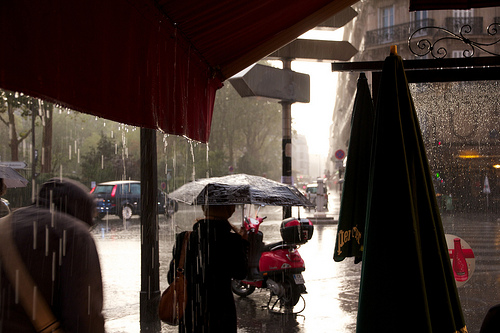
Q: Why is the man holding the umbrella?
A: It's raining.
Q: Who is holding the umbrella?
A: The person wearing black.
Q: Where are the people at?
A: On a sidewalk.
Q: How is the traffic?
A: Busy.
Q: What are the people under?
A: An awning.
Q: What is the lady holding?
A: An umbrella.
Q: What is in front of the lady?
A: The sidewalk.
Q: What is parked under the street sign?
A: A red scooter.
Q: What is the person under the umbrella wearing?
A: A black jacket.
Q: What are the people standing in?
A: The rain.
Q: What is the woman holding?
A: An umbrella.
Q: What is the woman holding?
A: A purse.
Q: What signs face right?
A: The top two.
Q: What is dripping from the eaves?
A: Rain water.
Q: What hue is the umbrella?
A: White and black.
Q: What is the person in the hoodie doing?
A: Walking in the rain.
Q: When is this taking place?
A: Daytime.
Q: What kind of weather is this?
A: Rain.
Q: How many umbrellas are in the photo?
A: One.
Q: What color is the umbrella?
A: Black.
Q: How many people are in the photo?
A: Two.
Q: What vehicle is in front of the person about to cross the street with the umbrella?
A: Motorcycle.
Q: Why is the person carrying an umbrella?
A: To avoid getting wet.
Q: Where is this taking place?
A: On the street corner.